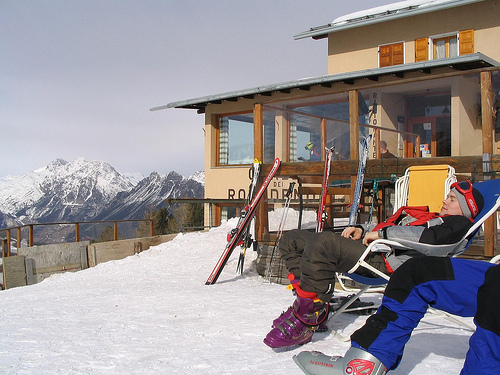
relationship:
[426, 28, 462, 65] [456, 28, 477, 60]
window has shutters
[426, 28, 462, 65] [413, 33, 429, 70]
window has shutters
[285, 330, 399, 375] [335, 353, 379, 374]
boots have design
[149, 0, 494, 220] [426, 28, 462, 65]
building has window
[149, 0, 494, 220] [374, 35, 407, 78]
building has window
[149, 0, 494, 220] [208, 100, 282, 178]
building has window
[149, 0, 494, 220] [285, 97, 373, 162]
building has windows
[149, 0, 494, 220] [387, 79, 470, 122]
building has window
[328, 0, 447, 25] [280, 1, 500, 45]
snow on roof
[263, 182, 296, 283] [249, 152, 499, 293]
poles on frame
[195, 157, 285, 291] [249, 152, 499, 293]
skis on frame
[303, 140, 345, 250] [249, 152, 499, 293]
skis on frame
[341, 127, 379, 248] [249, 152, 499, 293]
skis on frame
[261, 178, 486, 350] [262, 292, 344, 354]
man has purple skates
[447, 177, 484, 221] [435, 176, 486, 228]
goggles on head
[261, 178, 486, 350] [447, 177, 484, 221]
man has goggles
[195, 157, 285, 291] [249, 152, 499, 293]
skis against frame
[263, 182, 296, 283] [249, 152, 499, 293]
poles against frame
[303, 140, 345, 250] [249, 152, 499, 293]
skis against frame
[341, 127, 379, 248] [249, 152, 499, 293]
skis against frame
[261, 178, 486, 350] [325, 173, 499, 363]
man in chair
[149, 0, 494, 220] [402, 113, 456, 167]
building has doorway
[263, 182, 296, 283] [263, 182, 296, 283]
poles near poles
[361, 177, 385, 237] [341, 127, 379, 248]
ski poles near skis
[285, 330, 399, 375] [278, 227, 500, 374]
boots on person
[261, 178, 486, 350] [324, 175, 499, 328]
man reclining outdoors in chair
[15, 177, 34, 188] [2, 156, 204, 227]
snow on mountains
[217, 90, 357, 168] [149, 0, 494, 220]
windows in building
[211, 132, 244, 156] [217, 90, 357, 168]
curtains of windows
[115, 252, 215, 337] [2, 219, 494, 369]
snow on ground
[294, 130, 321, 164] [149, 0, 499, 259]
person indoors at building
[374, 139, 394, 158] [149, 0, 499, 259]
person indoors at building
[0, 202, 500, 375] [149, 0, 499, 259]
snow around building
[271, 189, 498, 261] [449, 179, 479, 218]
man wearing goggles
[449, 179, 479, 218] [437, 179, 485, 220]
goggles on head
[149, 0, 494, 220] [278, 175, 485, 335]
building near man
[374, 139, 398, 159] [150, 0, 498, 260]
person inside building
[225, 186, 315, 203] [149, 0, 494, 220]
word printed on building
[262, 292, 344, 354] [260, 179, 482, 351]
purple skates worn by man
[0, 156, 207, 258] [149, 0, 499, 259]
mountains next to building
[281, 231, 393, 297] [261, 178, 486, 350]
black pants covering legs of man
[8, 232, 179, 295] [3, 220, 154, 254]
stone base supporting fence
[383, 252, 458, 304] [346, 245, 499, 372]
patch on ski pants